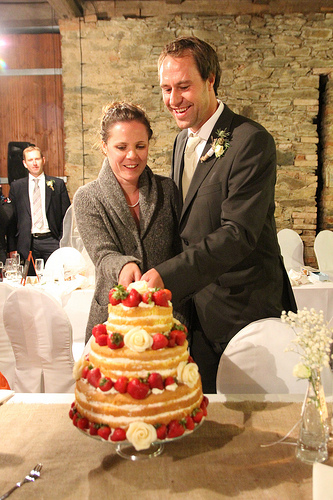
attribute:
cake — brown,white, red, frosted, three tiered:
[69, 280, 209, 450]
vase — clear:
[295, 372, 326, 464]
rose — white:
[121, 328, 155, 352]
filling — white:
[73, 301, 204, 430]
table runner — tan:
[0, 402, 332, 498]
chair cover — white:
[3, 288, 84, 391]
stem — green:
[113, 285, 127, 300]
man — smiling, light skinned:
[139, 35, 297, 393]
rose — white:
[125, 421, 158, 452]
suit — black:
[7, 174, 71, 276]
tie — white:
[180, 136, 201, 207]